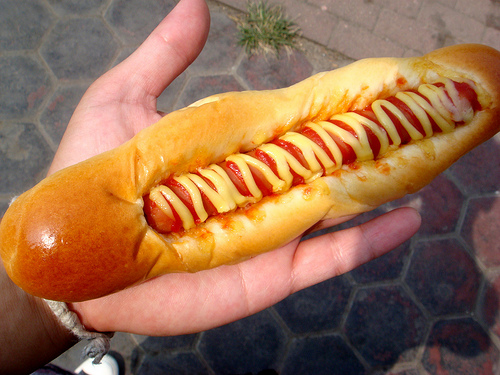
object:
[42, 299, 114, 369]
bracelet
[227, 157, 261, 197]
yarn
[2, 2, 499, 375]
ground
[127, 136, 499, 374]
shadow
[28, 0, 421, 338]
hand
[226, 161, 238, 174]
ketchup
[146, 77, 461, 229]
mustard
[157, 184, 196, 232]
cheese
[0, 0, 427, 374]
person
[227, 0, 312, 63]
weed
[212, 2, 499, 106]
sidewalk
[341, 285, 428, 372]
bricks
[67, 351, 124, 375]
shoe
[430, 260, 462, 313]
graffiti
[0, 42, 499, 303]
.sandwich